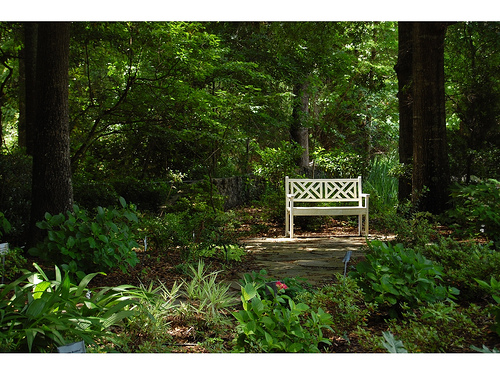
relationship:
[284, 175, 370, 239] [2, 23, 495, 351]
bench in woods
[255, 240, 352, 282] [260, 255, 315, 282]
shadow on ground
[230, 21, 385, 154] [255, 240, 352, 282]
trees casting shadow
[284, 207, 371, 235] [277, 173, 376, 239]
legs on bench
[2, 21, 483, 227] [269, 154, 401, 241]
trees behind bench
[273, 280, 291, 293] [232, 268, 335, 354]
pink flower in bush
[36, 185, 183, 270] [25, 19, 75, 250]
bush by tree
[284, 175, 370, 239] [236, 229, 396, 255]
bench in spot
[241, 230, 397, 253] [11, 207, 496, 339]
light on ground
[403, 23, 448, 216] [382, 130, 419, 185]
tree touching ground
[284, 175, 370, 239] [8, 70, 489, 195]
bench between forest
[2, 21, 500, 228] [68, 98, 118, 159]
trees with branches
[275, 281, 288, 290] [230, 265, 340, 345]
pink flower with plant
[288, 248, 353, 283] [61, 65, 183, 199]
shadow of tree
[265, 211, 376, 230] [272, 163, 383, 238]
stand of bench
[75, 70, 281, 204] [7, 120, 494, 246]
tree in forest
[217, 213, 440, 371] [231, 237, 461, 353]
dirt with plants